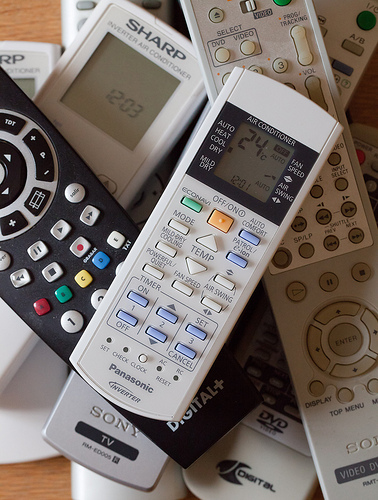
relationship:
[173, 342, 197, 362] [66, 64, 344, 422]
button on box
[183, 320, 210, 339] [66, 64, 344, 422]
button on box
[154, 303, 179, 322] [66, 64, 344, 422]
button on box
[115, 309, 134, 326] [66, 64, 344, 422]
button on box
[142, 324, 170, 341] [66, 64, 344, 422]
button on box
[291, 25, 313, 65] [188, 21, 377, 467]
button on remote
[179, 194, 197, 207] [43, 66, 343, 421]
button on remote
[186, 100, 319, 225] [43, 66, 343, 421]
display on remote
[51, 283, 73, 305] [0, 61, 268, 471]
green button on remote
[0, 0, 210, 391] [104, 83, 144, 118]
remote indicating 12:03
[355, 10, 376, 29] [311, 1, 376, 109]
button on remote control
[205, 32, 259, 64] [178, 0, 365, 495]
buttons on remote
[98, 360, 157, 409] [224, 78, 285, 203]
logo on remote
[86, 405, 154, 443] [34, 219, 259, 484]
logo on remote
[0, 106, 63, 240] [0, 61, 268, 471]
buttons on remote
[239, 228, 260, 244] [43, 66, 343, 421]
button on remote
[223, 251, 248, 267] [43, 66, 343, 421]
button on remote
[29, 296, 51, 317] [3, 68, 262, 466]
button on remot